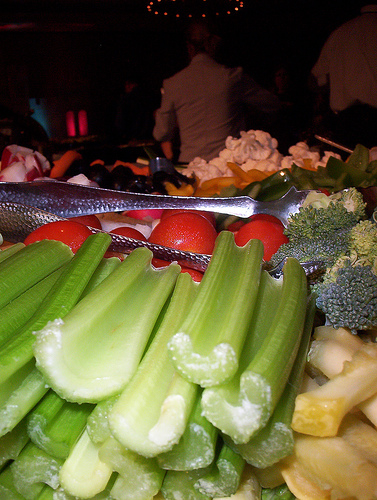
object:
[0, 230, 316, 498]
celery stalks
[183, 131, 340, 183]
cauliflower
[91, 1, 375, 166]
group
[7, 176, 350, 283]
tongs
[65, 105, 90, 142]
shaded lamp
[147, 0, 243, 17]
light fixture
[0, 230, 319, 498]
celery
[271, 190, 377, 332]
broccoli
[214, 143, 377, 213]
peppers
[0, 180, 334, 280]
utensil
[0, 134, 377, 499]
platter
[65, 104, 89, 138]
light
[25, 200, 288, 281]
cherry tomato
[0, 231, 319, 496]
celary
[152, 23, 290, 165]
woman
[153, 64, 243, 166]
back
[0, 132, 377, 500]
vegetables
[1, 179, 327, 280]
tong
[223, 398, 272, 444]
stuff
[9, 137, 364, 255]
fruits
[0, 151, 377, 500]
table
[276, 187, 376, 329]
head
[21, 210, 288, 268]
pile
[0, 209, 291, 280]
tomato